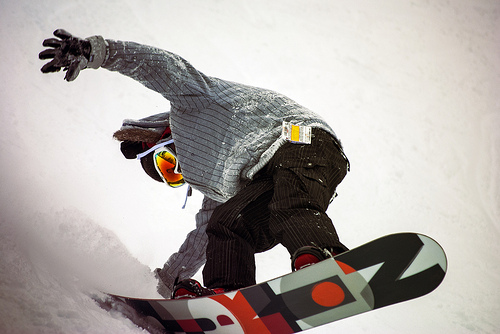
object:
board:
[88, 230, 449, 334]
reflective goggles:
[149, 145, 185, 191]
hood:
[113, 111, 170, 145]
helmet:
[138, 145, 185, 189]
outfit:
[85, 33, 348, 294]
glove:
[37, 28, 90, 83]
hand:
[37, 27, 89, 81]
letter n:
[332, 232, 446, 309]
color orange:
[154, 149, 187, 188]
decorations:
[93, 230, 449, 334]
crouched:
[37, 24, 350, 296]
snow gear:
[37, 26, 350, 299]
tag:
[281, 121, 313, 145]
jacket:
[87, 34, 340, 299]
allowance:
[280, 121, 313, 144]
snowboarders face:
[136, 143, 186, 188]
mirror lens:
[152, 150, 184, 189]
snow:
[64, 53, 89, 69]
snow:
[49, 243, 96, 303]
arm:
[153, 196, 221, 299]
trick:
[37, 28, 449, 332]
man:
[35, 28, 349, 298]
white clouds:
[407, 72, 454, 128]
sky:
[410, 54, 458, 104]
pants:
[201, 126, 349, 290]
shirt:
[87, 34, 336, 291]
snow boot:
[289, 240, 329, 270]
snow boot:
[170, 276, 223, 299]